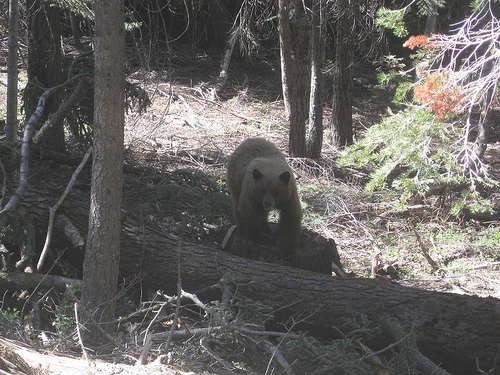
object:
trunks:
[276, 0, 307, 158]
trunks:
[306, 0, 323, 157]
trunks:
[331, 0, 352, 150]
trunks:
[22, 10, 66, 154]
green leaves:
[336, 104, 460, 210]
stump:
[219, 222, 331, 276]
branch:
[334, 0, 500, 216]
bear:
[227, 137, 303, 260]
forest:
[0, 0, 500, 316]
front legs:
[277, 198, 303, 248]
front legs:
[239, 190, 261, 234]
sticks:
[113, 289, 353, 375]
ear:
[280, 171, 291, 184]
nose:
[263, 201, 272, 208]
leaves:
[413, 73, 466, 118]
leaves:
[403, 34, 427, 50]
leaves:
[373, 5, 410, 38]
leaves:
[52, 288, 76, 335]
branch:
[403, 0, 418, 9]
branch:
[74, 303, 90, 364]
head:
[251, 169, 290, 211]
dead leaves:
[423, 1, 500, 183]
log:
[0, 180, 500, 375]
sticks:
[412, 227, 438, 275]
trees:
[77, 0, 126, 345]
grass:
[130, 165, 224, 229]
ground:
[0, 137, 497, 374]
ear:
[253, 169, 263, 181]